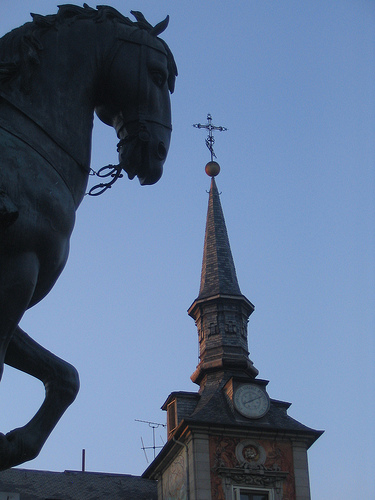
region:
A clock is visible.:
[223, 365, 289, 452]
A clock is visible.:
[211, 351, 266, 442]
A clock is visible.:
[202, 382, 270, 462]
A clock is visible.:
[204, 337, 330, 491]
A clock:
[185, 292, 295, 464]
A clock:
[173, 310, 250, 487]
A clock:
[231, 342, 263, 481]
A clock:
[203, 326, 264, 472]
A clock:
[212, 310, 257, 422]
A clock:
[237, 323, 276, 420]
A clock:
[237, 301, 287, 467]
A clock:
[221, 337, 279, 496]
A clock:
[219, 334, 246, 490]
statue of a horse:
[15, 14, 227, 409]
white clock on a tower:
[219, 361, 273, 431]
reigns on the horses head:
[2, 91, 135, 217]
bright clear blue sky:
[272, 100, 351, 245]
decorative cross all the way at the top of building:
[184, 112, 241, 184]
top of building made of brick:
[182, 178, 243, 302]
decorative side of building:
[189, 420, 323, 492]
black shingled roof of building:
[25, 461, 150, 494]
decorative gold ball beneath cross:
[194, 159, 228, 182]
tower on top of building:
[182, 128, 275, 358]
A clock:
[214, 352, 329, 484]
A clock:
[204, 381, 255, 495]